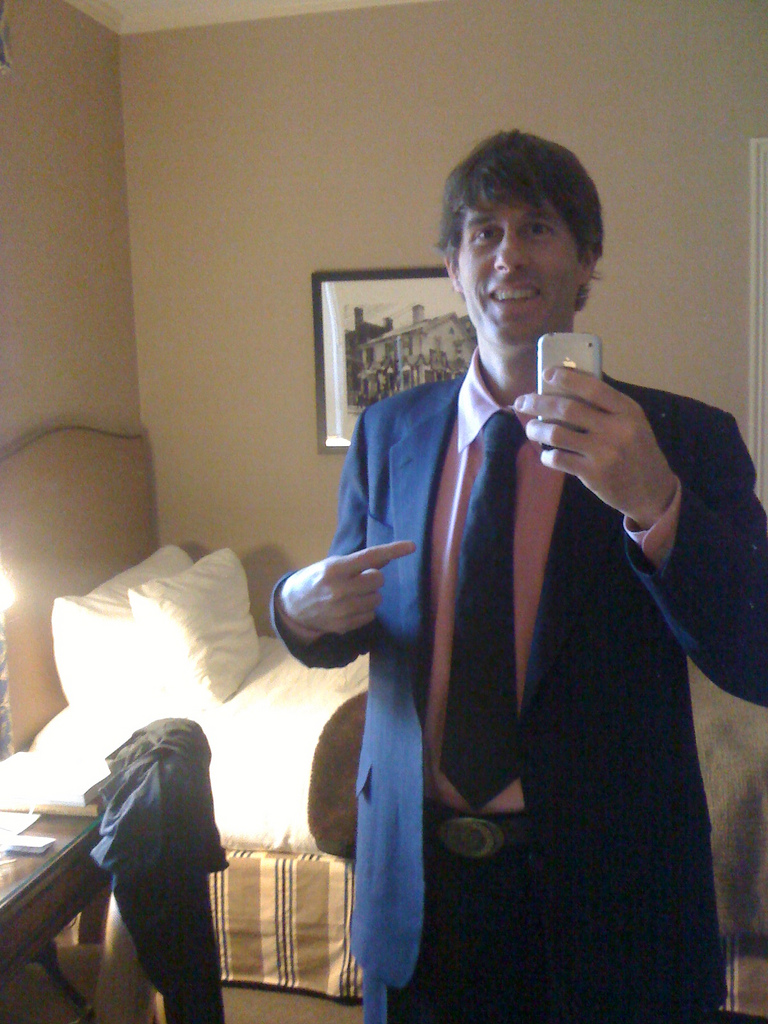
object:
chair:
[0, 709, 186, 1023]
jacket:
[82, 715, 229, 1024]